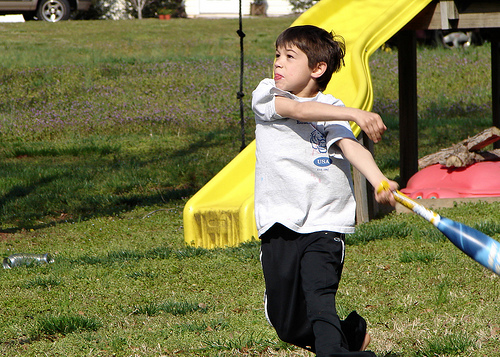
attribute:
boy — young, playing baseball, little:
[253, 28, 369, 338]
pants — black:
[259, 234, 349, 354]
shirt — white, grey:
[257, 98, 365, 249]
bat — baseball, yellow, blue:
[393, 194, 498, 275]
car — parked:
[4, 1, 90, 25]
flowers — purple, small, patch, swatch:
[45, 106, 178, 141]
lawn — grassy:
[11, 25, 278, 156]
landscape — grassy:
[9, 25, 471, 197]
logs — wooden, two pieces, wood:
[410, 126, 498, 177]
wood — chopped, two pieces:
[423, 117, 498, 161]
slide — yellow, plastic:
[176, 6, 411, 241]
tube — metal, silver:
[2, 248, 54, 271]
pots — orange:
[157, 15, 175, 21]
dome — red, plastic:
[404, 166, 497, 198]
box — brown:
[248, 2, 270, 19]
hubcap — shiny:
[47, 3, 61, 19]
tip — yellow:
[375, 178, 390, 194]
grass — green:
[5, 37, 226, 184]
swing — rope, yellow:
[238, 4, 242, 141]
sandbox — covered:
[384, 24, 498, 181]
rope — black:
[233, 10, 250, 148]